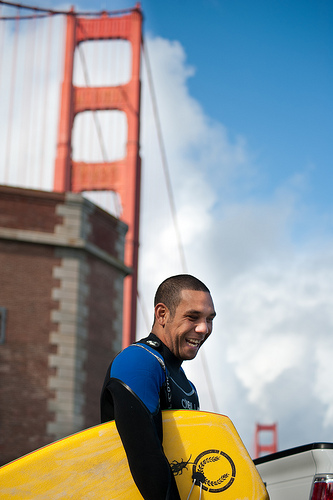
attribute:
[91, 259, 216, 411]
man — laughing, smiling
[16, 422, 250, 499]
surfboard — yellow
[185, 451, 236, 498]
logo — black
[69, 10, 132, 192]
bridge support — red, orange, famous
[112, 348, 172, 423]
wetsuit — black, blue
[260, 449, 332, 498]
truck — white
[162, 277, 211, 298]
hair — short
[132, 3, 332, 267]
sky — clear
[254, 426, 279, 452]
bridge support — orange